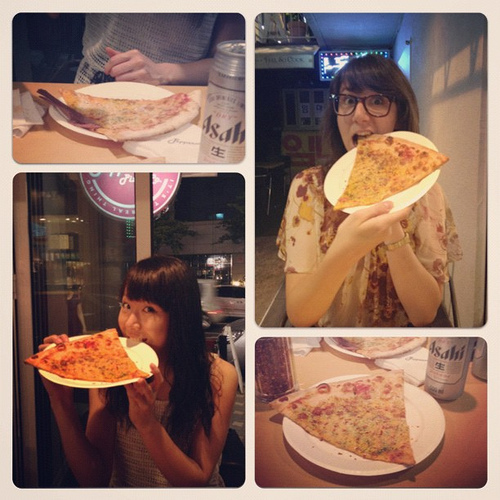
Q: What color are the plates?
A: White.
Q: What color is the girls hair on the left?
A: Black.